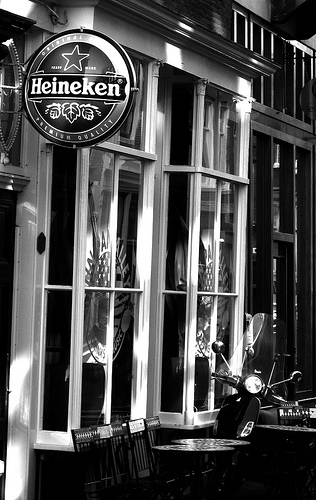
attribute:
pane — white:
[80, 290, 108, 434]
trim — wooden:
[193, 81, 251, 184]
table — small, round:
[174, 436, 249, 494]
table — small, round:
[149, 442, 232, 499]